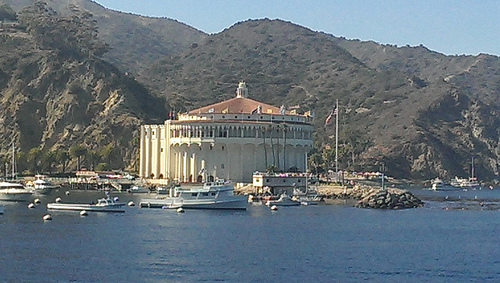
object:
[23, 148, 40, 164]
leaves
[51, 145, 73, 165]
leaves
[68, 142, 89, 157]
leaves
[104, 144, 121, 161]
leaves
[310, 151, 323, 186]
tree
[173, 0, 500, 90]
sky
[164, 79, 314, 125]
roof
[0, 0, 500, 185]
mountain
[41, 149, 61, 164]
leaves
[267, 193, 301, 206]
boat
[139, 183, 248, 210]
boat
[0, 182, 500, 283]
water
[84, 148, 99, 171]
tree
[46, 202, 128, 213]
boat